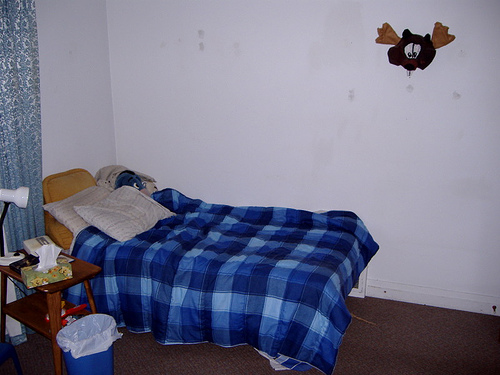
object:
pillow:
[42, 186, 112, 238]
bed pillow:
[72, 184, 177, 243]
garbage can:
[55, 313, 124, 375]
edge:
[71, 236, 332, 300]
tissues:
[34, 244, 62, 271]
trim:
[367, 278, 500, 317]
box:
[21, 259, 74, 289]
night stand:
[0, 249, 102, 375]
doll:
[114, 169, 150, 197]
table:
[0, 248, 102, 375]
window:
[0, 0, 43, 225]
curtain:
[0, 0, 46, 335]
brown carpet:
[0, 295, 500, 375]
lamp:
[0, 186, 30, 266]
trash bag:
[55, 313, 123, 359]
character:
[375, 21, 457, 79]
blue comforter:
[65, 188, 379, 375]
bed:
[42, 167, 379, 375]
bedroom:
[0, 0, 500, 375]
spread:
[62, 187, 378, 375]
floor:
[0, 294, 500, 375]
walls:
[35, 0, 500, 315]